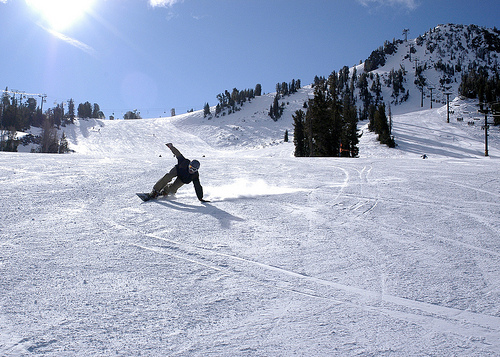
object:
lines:
[322, 163, 350, 203]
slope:
[0, 151, 498, 356]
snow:
[0, 24, 499, 356]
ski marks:
[356, 216, 500, 259]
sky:
[0, 0, 498, 120]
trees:
[455, 66, 470, 97]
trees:
[288, 109, 308, 156]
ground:
[0, 151, 499, 355]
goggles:
[190, 166, 199, 172]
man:
[133, 142, 213, 205]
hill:
[0, 22, 499, 158]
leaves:
[316, 115, 321, 122]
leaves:
[383, 128, 388, 132]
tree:
[348, 100, 362, 158]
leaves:
[316, 143, 324, 150]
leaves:
[273, 106, 279, 113]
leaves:
[471, 83, 477, 87]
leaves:
[6, 116, 14, 122]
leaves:
[79, 108, 83, 111]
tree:
[36, 115, 53, 154]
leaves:
[366, 63, 373, 66]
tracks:
[99, 205, 499, 353]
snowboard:
[132, 190, 164, 203]